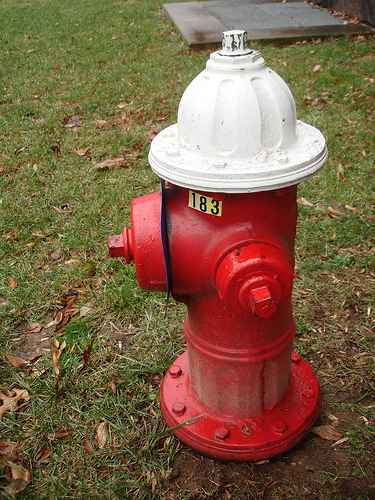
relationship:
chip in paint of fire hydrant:
[239, 422, 250, 436] [106, 29, 327, 459]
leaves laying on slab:
[325, 5, 360, 31] [162, 0, 355, 51]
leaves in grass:
[89, 415, 112, 451] [310, 214, 360, 259]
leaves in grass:
[5, 358, 31, 415] [310, 214, 360, 259]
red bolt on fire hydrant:
[214, 425, 229, 438] [106, 29, 327, 459]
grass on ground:
[4, 3, 148, 183] [11, 100, 362, 487]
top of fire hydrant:
[147, 28, 327, 194] [106, 29, 327, 459]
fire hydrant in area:
[127, 100, 318, 393] [5, 2, 365, 498]